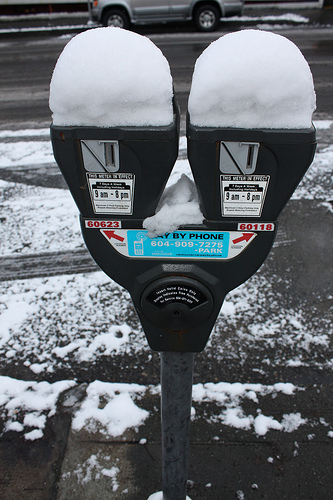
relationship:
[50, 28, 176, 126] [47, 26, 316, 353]
snow on top of parking meter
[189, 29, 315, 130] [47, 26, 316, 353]
snow on top of parking meter